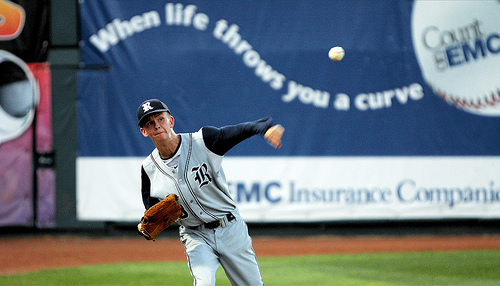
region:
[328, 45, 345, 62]
white with red baseball flying through air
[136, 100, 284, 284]
baseball pitcher throwing baseball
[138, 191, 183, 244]
brown baseball glove on baseball player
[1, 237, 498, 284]
baseball field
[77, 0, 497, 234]
blue and white business advertisement on wall in background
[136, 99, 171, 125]
Navy blue baseball cap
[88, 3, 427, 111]
When life throws you a curve written on banner in background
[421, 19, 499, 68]
Count on EMC written on baseball in ad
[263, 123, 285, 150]
hand throwing baseball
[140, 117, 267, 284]
gray and navy blue baseball uniform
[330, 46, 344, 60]
A baseball in the air.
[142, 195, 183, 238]
A brown baseball mitt.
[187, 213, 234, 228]
A black belt.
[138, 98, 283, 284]
A baseball player.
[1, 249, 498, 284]
A green field.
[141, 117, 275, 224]
A shit with dark colored sleeves.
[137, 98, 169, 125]
A dark colored baseball cap.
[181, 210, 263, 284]
A pair of light gray pants.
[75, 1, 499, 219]
A banner in the background.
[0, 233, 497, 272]
A light brown dirt.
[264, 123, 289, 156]
the pitching hand of the player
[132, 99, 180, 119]
the pitcher's baseball cap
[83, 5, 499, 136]
the EMC ad in the background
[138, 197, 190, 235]
the glove on the pitcher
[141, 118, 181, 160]
the pitcher's face after throwing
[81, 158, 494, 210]
the white insurance company background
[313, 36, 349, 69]
the ball being thrown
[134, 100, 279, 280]
the player on the grass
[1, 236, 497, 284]
the warning track in the outfield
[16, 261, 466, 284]
the grass by the outfielder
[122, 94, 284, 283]
man throwing baseball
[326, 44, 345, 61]
baseball flying thru the air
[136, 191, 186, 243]
baseball mitt in players hand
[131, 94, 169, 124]
baseball cap on players head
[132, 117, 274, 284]
baseball players uniform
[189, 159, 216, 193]
letter R on players uniform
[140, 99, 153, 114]
Letter R on players baseball cap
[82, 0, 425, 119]
saying on billboard behind player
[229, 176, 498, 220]
name of sponsor on billboard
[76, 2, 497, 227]
billboard behind player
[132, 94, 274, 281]
Baseball player in the forefront.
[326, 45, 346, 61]
Baseball in the air.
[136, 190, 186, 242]
Mitt on the hand.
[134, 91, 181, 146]
Man wearing a hat.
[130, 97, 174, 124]
Black and white hat.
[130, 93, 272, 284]
black and grey uniform.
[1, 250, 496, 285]
Green grass on the ground.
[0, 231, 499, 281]
Dirt on the ground.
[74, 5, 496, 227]
sign in the background.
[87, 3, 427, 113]
White writing on the sign.